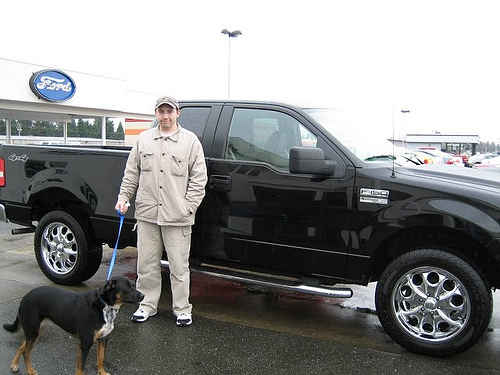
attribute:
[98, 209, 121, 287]
leash — blue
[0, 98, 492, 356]
truck — black, 4x4, pick up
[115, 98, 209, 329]
man — standing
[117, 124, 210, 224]
jacket — beige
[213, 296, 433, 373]
ground — wet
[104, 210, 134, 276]
leash — blue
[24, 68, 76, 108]
sign — blue, white, oval, Ford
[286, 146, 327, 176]
mirror — rear view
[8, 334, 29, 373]
leg — hind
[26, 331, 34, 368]
leg — hind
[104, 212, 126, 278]
leash — blue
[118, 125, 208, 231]
jacket — tan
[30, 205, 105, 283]
wheel — rear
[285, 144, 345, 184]
mirror — side, rear view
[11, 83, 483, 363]
truck — shiny, black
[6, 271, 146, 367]
dog — black, brown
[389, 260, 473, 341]
rims — silver, tire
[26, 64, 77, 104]
name — brand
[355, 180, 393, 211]
emblems — silver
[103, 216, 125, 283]
leash — blue, dog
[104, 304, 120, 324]
spots — black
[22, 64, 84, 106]
sign — Ford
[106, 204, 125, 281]
leash — blue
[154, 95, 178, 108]
hat — beige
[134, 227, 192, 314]
pants — beige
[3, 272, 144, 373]
dog — black, brown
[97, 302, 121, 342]
patch — white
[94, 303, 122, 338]
area — chest, his